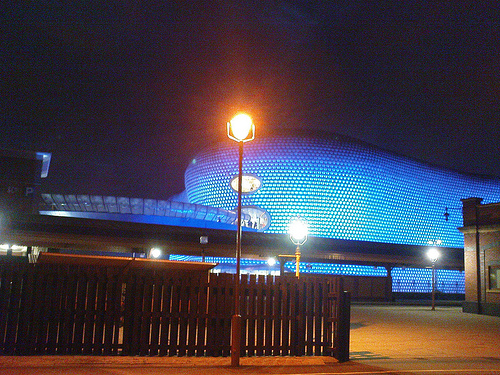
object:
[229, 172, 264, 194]
light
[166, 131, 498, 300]
building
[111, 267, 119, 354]
pole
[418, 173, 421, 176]
light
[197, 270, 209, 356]
pole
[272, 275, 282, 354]
pole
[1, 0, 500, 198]
sky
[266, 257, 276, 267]
bright light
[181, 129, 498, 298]
patterned brickwork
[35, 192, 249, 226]
cover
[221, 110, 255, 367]
street lamp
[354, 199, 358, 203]
light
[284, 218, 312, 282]
pole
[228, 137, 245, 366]
pole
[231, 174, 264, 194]
window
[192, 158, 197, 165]
light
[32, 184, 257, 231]
stage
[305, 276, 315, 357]
pole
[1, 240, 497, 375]
walkway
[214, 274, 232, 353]
pole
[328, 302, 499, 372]
ground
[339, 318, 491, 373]
reflection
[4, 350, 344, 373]
curb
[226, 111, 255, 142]
light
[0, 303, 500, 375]
pavement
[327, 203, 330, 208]
light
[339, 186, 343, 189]
light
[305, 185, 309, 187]
light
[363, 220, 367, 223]
light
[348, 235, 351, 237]
light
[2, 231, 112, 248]
cement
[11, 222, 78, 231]
brick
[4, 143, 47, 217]
building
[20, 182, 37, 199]
sign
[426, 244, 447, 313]
light pole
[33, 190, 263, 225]
hallway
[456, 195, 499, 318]
building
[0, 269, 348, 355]
fence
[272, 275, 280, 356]
pole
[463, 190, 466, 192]
light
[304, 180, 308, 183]
light